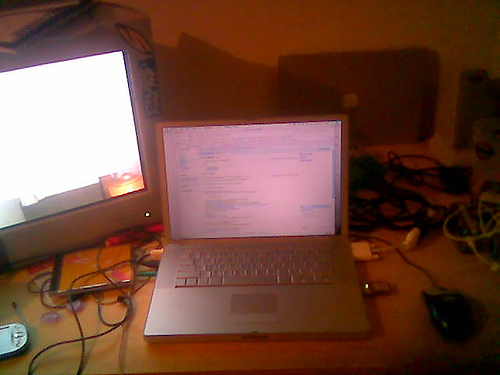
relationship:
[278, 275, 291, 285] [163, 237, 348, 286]
button on keyboard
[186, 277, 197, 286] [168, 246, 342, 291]
key on keyboard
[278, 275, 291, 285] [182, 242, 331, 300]
button on keyboard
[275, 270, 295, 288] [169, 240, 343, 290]
button on keyboard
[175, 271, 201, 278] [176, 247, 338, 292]
key on keyboard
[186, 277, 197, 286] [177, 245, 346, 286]
key on keyboard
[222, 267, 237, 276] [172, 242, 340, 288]
key on keyboard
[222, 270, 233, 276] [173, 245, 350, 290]
key on keyboard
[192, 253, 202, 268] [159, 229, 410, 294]
key on keyboard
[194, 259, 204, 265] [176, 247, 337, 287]
key on keyboard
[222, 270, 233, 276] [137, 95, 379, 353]
key on keyboard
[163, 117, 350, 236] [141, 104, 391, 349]
screen next to laptop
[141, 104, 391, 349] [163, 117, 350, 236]
laptop next to screen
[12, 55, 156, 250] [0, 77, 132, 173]
screen has light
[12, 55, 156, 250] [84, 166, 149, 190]
screen has picture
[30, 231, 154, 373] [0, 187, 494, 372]
black wire looping over table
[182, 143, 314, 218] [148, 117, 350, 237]
print on screen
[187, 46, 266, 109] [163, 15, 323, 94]
shadow falling against wall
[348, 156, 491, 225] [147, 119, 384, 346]
wires behind laptop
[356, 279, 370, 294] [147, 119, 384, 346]
light on side of laptop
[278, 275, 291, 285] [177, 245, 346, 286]
button on keyboard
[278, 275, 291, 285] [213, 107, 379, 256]
button on laptop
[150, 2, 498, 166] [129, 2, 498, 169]
wall on building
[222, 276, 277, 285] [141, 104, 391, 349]
key on laptop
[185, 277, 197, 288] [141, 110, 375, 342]
key on laptop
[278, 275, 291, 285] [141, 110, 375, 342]
button on laptop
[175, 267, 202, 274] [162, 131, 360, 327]
key on laptop